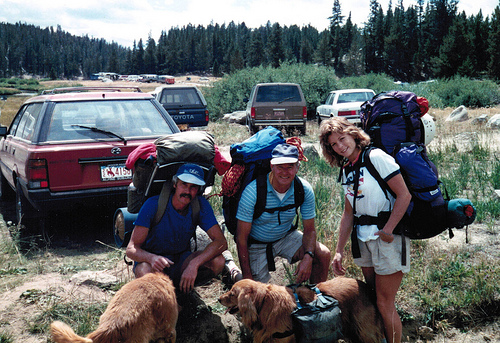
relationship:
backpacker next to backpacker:
[125, 162, 228, 277] [233, 139, 333, 287]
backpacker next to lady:
[233, 139, 333, 287] [313, 117, 411, 343]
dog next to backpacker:
[48, 262, 178, 342] [125, 162, 228, 277]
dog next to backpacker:
[215, 276, 381, 342] [233, 139, 333, 287]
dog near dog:
[48, 273, 177, 341] [219, 268, 393, 335]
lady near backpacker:
[313, 117, 411, 343] [233, 144, 333, 286]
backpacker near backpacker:
[233, 144, 333, 286] [125, 162, 229, 292]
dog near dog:
[215, 276, 381, 342] [48, 273, 177, 341]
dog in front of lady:
[215, 276, 381, 342] [313, 117, 411, 343]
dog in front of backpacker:
[48, 273, 177, 341] [233, 144, 333, 286]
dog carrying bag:
[215, 276, 381, 342] [289, 282, 348, 343]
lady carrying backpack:
[313, 117, 411, 343] [348, 91, 482, 242]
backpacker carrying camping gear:
[125, 162, 229, 292] [110, 129, 230, 249]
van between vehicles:
[242, 67, 317, 139] [147, 76, 397, 150]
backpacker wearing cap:
[125, 162, 229, 292] [175, 163, 207, 188]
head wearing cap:
[171, 167, 204, 205] [175, 163, 207, 188]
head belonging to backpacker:
[171, 167, 204, 205] [125, 162, 229, 292]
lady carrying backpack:
[313, 117, 438, 341] [381, 84, 470, 246]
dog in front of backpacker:
[48, 273, 177, 341] [125, 162, 229, 292]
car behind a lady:
[311, 85, 379, 125] [313, 117, 411, 343]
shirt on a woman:
[337, 150, 412, 232] [325, 123, 419, 329]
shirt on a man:
[119, 172, 236, 270] [222, 115, 312, 281]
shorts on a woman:
[353, 234, 411, 276] [317, 114, 413, 341]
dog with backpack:
[211, 268, 381, 342] [361, 79, 483, 245]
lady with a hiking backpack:
[313, 117, 411, 343] [365, 76, 480, 272]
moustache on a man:
[169, 193, 188, 207] [114, 125, 272, 340]